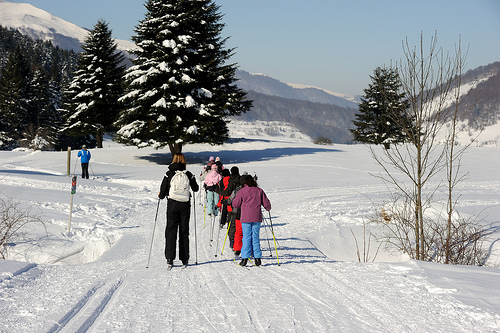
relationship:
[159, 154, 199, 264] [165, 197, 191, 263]
woman wearing pants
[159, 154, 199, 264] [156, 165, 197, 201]
woman wearing jacket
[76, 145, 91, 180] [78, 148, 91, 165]
man wearing jacket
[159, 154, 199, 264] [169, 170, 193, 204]
woman wearing backpack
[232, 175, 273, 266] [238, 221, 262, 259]
person wearing pants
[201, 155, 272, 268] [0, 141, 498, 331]
people on snow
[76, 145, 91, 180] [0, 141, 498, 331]
man on snow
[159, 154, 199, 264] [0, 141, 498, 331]
woman on snow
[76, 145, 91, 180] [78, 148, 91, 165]
man wearing a jacket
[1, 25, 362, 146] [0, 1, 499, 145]
trees are on mountain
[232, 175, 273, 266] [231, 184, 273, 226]
person wearing jacket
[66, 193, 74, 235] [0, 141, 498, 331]
sign post stuck into snow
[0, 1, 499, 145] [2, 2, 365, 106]
mountain covered with snow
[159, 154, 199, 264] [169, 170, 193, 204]
woman wearing a backpack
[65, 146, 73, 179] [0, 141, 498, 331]
pole in snow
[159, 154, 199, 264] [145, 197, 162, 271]
woman holding ski pole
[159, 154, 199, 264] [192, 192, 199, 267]
woman holding ski pole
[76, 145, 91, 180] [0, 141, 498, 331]
man standing in snow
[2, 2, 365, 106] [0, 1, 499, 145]
snow on mountain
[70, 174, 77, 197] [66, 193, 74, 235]
sign on a sign post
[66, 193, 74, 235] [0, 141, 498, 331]
sign post on snow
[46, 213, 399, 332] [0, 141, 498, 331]
tracks are in snow